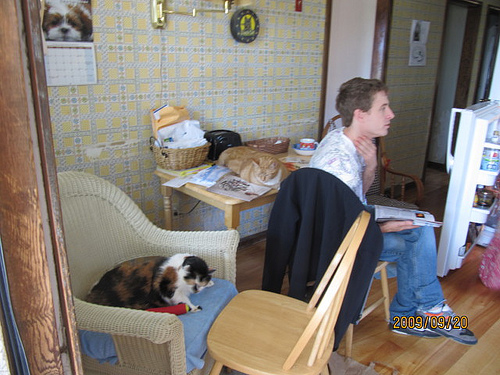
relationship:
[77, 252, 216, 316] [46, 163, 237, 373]
cat sleeping on chair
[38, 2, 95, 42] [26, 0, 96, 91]
dog on calender